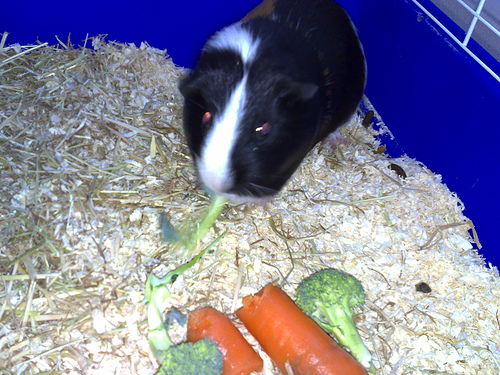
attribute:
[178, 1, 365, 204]
guinea pig — White 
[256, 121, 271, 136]
eye — red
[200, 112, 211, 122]
eye — red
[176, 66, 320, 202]
guinea pig — black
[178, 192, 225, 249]
vegetable — green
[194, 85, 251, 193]
stripe — white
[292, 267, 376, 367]
broccoli — small, green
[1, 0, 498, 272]
wall — plain, blue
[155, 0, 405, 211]
guinea pig — black, white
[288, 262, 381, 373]
broccoli — green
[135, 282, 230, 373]
broccoli — green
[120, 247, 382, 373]
veggies — green, orange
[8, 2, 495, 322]
cage — white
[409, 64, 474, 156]
wall — blue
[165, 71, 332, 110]
ears — black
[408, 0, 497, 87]
cage wall — white, wire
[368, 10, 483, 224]
container — blue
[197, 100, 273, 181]
face — white